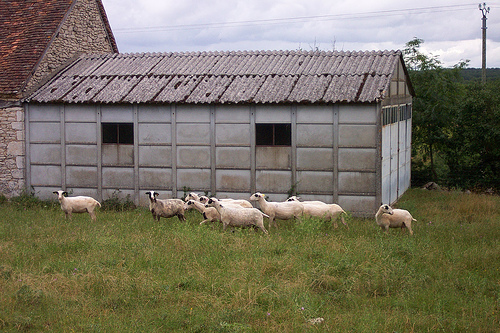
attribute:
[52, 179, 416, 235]
goats — white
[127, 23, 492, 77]
sky — cloudy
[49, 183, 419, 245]
sheep — white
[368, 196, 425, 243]
animal — white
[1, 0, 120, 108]
roof — brown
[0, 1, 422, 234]
building — grey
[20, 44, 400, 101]
roof — grey, picketed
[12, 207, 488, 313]
field — green